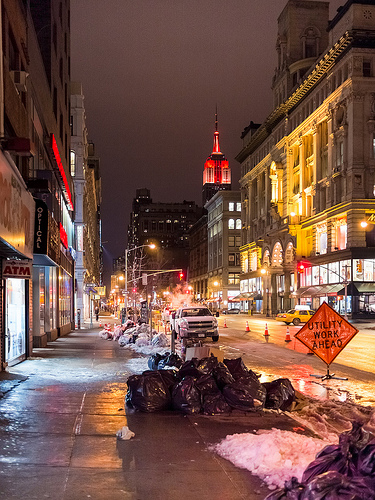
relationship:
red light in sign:
[297, 261, 311, 280] [294, 298, 357, 386]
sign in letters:
[3, 263, 34, 280] [0, 264, 28, 275]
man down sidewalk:
[94, 305, 98, 319] [0, 309, 322, 498]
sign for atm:
[3, 263, 34, 280] [0, 349, 53, 401]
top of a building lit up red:
[203, 107, 232, 187] [56, 225, 82, 267]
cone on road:
[219, 315, 228, 328] [346, 340, 373, 368]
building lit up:
[197, 101, 233, 210] [83, 185, 91, 300]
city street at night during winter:
[75, 255, 134, 470] [202, 430, 300, 500]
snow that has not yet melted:
[222, 415, 320, 481] [210, 425, 295, 495]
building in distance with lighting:
[197, 101, 233, 210] [251, 148, 313, 237]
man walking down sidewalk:
[94, 305, 98, 319] [4, 315, 137, 496]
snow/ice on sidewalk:
[32, 308, 373, 485] [4, 315, 137, 496]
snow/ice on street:
[32, 308, 373, 485] [214, 304, 374, 400]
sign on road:
[290, 299, 363, 387] [210, 308, 374, 413]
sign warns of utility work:
[290, 299, 363, 387] [289, 298, 361, 382]